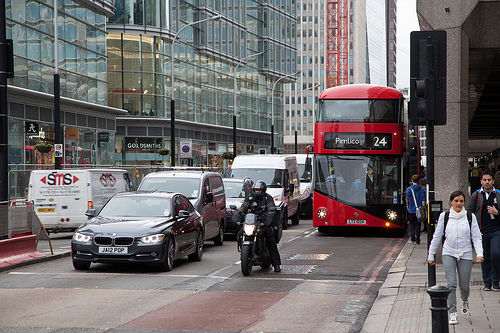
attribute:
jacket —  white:
[419, 212, 489, 271]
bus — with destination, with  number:
[318, 78, 422, 233]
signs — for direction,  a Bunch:
[177, 134, 195, 162]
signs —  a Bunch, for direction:
[160, 289, 246, 314]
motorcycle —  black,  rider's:
[229, 201, 293, 278]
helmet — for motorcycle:
[249, 178, 270, 200]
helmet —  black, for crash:
[249, 177, 266, 190]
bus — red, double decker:
[313, 82, 410, 232]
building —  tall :
[0, 3, 288, 238]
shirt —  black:
[426, 205, 483, 258]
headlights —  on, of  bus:
[386, 208, 396, 220]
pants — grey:
[434, 245, 474, 320]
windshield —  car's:
[93, 195, 171, 217]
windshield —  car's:
[134, 176, 201, 193]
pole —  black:
[427, 130, 444, 292]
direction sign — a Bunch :
[180, 135, 193, 159]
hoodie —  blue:
[405, 182, 426, 211]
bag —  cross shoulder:
[409, 186, 426, 221]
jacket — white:
[428, 205, 485, 255]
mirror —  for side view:
[174, 205, 188, 219]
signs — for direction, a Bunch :
[50, 143, 67, 160]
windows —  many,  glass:
[57, 40, 116, 77]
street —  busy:
[3, 263, 364, 332]